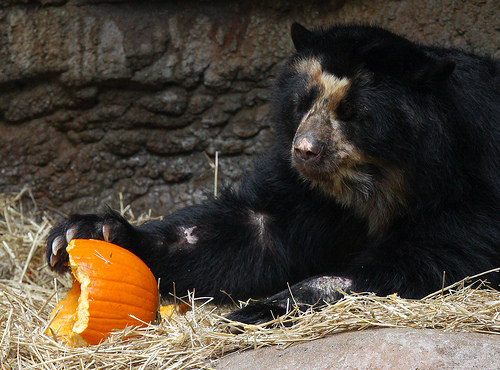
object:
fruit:
[44, 237, 164, 348]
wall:
[450, 11, 494, 43]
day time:
[1, 2, 498, 367]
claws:
[42, 219, 112, 268]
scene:
[25, 27, 475, 354]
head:
[276, 20, 457, 193]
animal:
[43, 19, 498, 334]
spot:
[304, 277, 357, 292]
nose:
[284, 139, 326, 173]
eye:
[337, 103, 357, 120]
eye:
[288, 101, 303, 117]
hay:
[361, 289, 498, 325]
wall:
[1, 6, 274, 234]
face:
[282, 54, 405, 183]